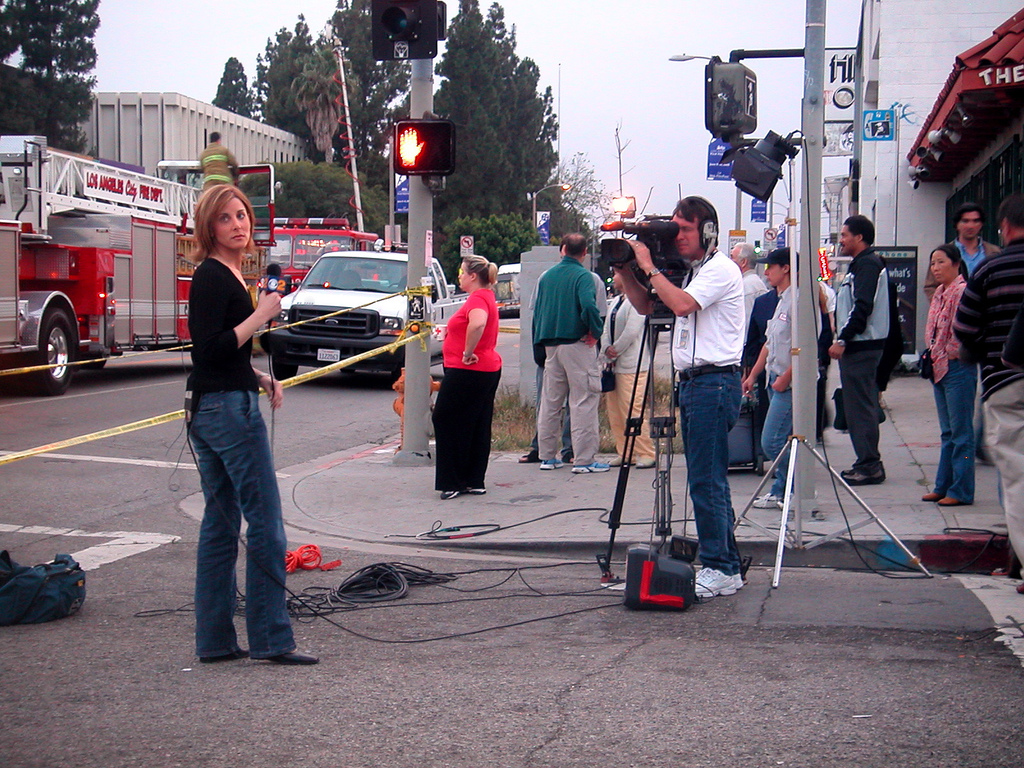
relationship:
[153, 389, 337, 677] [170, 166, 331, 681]
pants on lady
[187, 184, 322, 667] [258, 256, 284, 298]
lady holding microphone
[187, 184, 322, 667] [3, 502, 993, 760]
lady standing in street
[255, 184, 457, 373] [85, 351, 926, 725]
truck on street